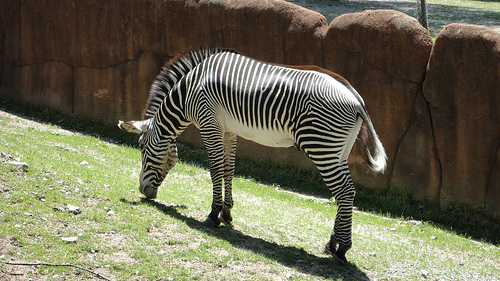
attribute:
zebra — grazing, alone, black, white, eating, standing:
[109, 47, 389, 258]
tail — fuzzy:
[358, 104, 388, 172]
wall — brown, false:
[1, 2, 500, 216]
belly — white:
[219, 111, 296, 145]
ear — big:
[115, 116, 153, 134]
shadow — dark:
[1, 92, 500, 240]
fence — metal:
[319, 2, 498, 23]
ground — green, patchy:
[4, 101, 496, 278]